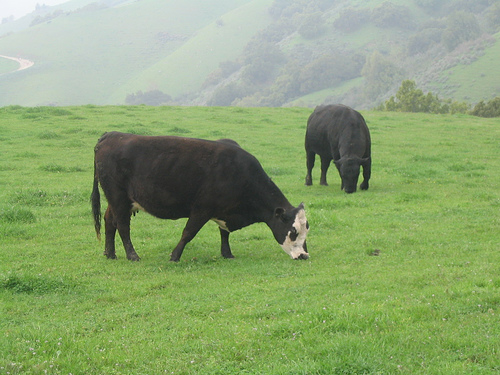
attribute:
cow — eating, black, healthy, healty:
[294, 100, 391, 209]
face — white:
[284, 198, 313, 264]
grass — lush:
[335, 196, 390, 225]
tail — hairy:
[88, 141, 109, 235]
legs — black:
[100, 201, 255, 274]